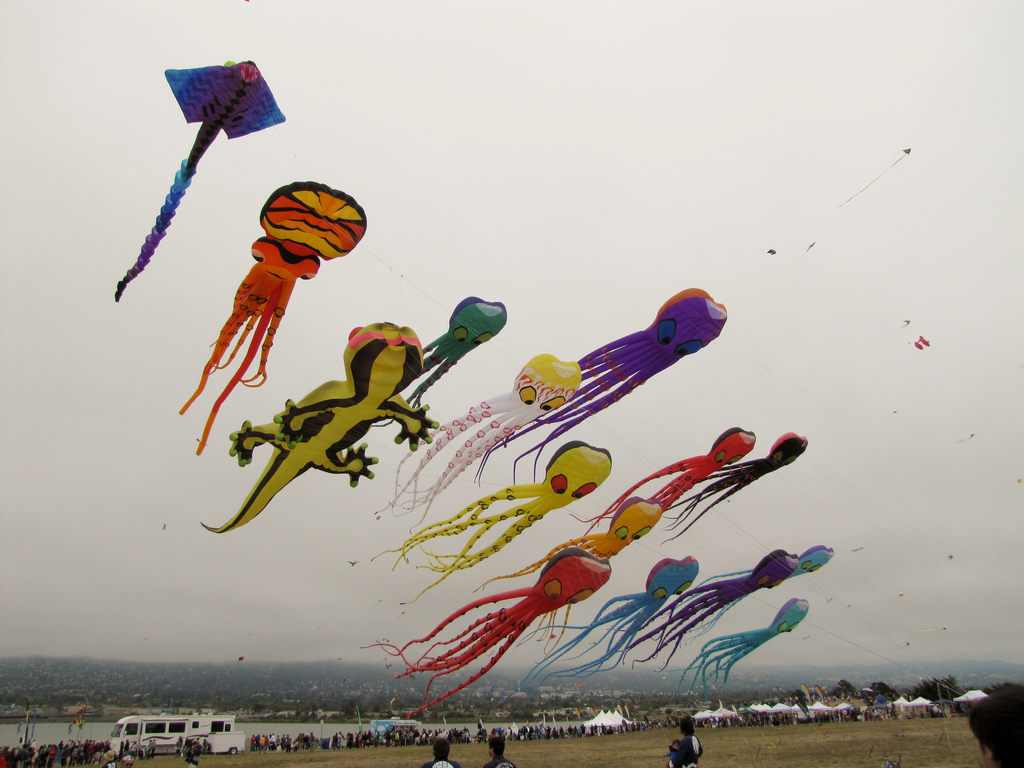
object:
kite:
[670, 598, 809, 699]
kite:
[116, 60, 287, 305]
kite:
[179, 180, 369, 456]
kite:
[200, 323, 441, 535]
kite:
[523, 556, 698, 685]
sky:
[370, 11, 1005, 324]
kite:
[371, 296, 507, 427]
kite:
[374, 353, 581, 535]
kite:
[475, 288, 727, 483]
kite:
[371, 440, 612, 603]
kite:
[582, 425, 757, 536]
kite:
[473, 496, 663, 654]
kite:
[628, 549, 801, 674]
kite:
[678, 544, 833, 642]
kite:
[662, 432, 808, 542]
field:
[33, 707, 1024, 765]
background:
[21, 1, 1024, 631]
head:
[970, 682, 1023, 767]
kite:
[409, 532, 615, 701]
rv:
[108, 715, 235, 758]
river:
[2, 724, 585, 751]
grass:
[748, 723, 964, 768]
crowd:
[254, 694, 951, 749]